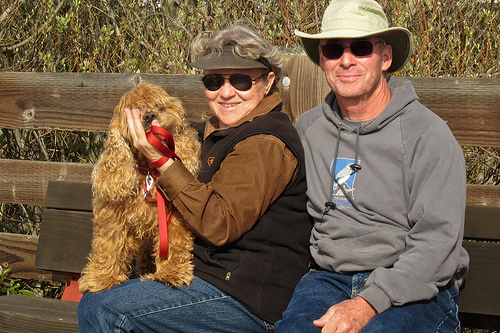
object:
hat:
[292, 1, 416, 73]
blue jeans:
[276, 272, 461, 332]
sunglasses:
[198, 72, 267, 91]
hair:
[189, 24, 289, 67]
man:
[275, 0, 470, 331]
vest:
[182, 104, 312, 323]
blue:
[145, 297, 191, 320]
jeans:
[74, 275, 265, 333]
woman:
[70, 25, 307, 333]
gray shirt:
[291, 76, 471, 314]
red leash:
[145, 125, 175, 260]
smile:
[213, 99, 248, 113]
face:
[202, 66, 263, 125]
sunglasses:
[319, 39, 387, 60]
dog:
[75, 80, 204, 296]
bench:
[0, 179, 499, 331]